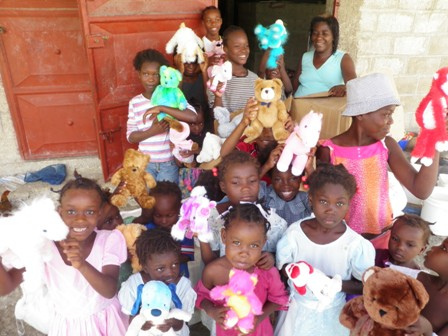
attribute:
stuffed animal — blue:
[256, 17, 292, 71]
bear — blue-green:
[148, 58, 188, 123]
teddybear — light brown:
[240, 77, 289, 142]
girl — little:
[310, 73, 447, 238]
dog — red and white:
[280, 258, 345, 306]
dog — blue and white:
[130, 279, 184, 334]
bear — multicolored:
[209, 268, 262, 330]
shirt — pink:
[321, 138, 391, 234]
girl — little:
[316, 72, 440, 249]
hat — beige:
[341, 70, 402, 115]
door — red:
[7, 3, 257, 149]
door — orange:
[2, 6, 99, 150]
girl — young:
[0, 167, 128, 334]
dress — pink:
[14, 228, 126, 334]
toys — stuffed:
[224, 71, 333, 180]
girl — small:
[116, 227, 194, 334]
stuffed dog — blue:
[124, 280, 191, 334]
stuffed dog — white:
[283, 259, 345, 317]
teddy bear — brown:
[242, 77, 291, 143]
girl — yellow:
[194, 200, 283, 335]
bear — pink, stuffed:
[206, 266, 259, 335]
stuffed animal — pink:
[211, 265, 260, 334]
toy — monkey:
[236, 67, 307, 159]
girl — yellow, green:
[127, 47, 199, 140]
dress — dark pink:
[317, 135, 395, 241]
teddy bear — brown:
[238, 80, 293, 149]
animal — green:
[138, 67, 191, 124]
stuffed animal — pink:
[201, 263, 280, 334]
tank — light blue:
[289, 48, 362, 98]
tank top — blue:
[301, 48, 347, 91]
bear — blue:
[155, 68, 182, 107]